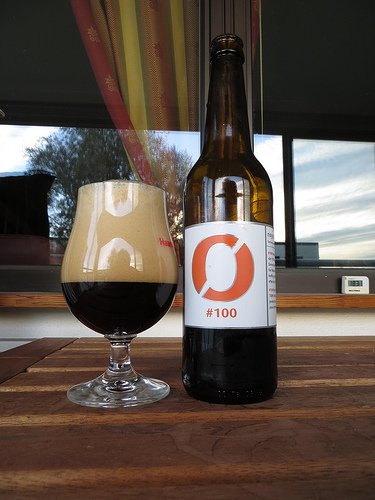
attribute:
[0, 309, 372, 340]
wall — white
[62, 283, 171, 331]
brown beer — foaming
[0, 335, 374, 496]
table — brown, slatted , wood, wooden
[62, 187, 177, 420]
wine glass — full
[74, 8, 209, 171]
curtain — gold, red, damask style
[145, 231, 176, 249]
writing — red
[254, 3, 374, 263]
window — glass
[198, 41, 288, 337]
glass — wine glass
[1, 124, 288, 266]
window — pictured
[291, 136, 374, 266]
window — pictured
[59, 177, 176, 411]
glass — wine glass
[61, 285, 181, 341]
beer — brown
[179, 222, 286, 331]
label — red, white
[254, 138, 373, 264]
jet trails — white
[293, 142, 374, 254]
cloudy — partially